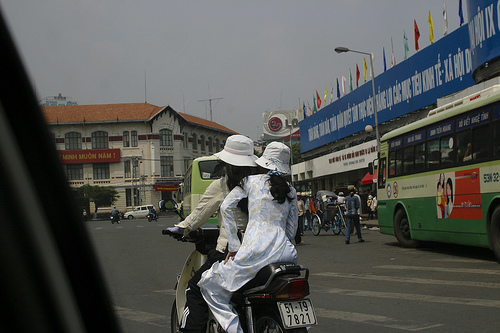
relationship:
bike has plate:
[160, 224, 318, 333] [279, 299, 319, 328]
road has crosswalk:
[84, 215, 500, 333] [326, 263, 476, 323]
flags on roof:
[302, 0, 463, 119] [285, 15, 484, 96]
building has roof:
[282, 91, 484, 237] [285, 15, 484, 96]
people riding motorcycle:
[199, 141, 298, 333] [230, 264, 317, 331]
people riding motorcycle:
[199, 141, 298, 333] [162, 222, 319, 332]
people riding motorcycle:
[167, 135, 260, 333] [162, 222, 319, 332]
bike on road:
[160, 224, 318, 333] [121, 209, 484, 321]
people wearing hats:
[167, 128, 304, 332] [209, 132, 299, 177]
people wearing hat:
[167, 135, 260, 333] [214, 133, 258, 165]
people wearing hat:
[199, 141, 298, 333] [254, 140, 291, 174]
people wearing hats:
[204, 136, 298, 313] [221, 115, 299, 172]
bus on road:
[377, 119, 499, 241] [91, 205, 490, 330]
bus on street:
[377, 77, 500, 260] [324, 232, 481, 322]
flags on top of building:
[477, 0, 500, 37] [266, 38, 484, 231]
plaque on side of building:
[65, 145, 121, 163] [49, 79, 229, 297]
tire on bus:
[390, 203, 422, 252] [374, 98, 484, 250]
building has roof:
[44, 99, 184, 219] [39, 103, 154, 119]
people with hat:
[199, 141, 298, 333] [255, 140, 296, 173]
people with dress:
[199, 141, 298, 333] [246, 176, 286, 260]